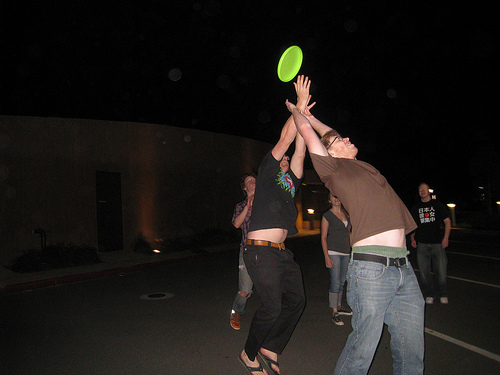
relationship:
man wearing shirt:
[288, 98, 425, 374] [310, 156, 416, 243]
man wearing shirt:
[244, 77, 316, 375] [245, 153, 301, 231]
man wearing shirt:
[416, 183, 452, 303] [416, 199, 451, 242]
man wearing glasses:
[288, 98, 425, 374] [326, 133, 342, 147]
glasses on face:
[326, 133, 342, 147] [327, 133, 359, 158]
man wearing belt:
[288, 98, 425, 374] [351, 252, 409, 265]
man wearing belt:
[244, 77, 316, 375] [245, 240, 290, 248]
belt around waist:
[351, 252, 409, 265] [350, 247, 413, 268]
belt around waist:
[245, 240, 290, 248] [243, 236, 292, 252]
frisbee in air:
[276, 44, 303, 81] [0, 1, 499, 230]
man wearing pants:
[244, 77, 316, 375] [243, 245, 306, 360]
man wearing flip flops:
[244, 77, 316, 375] [236, 351, 283, 374]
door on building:
[96, 168, 123, 255] [1, 118, 289, 248]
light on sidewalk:
[152, 250, 160, 255] [0, 252, 213, 282]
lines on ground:
[423, 246, 499, 362] [1, 232, 500, 374]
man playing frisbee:
[288, 98, 425, 374] [276, 44, 303, 81]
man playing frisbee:
[244, 77, 316, 375] [276, 44, 303, 81]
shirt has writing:
[416, 199, 451, 242] [417, 206, 435, 224]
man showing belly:
[288, 98, 425, 374] [354, 230, 408, 248]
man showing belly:
[244, 77, 316, 375] [248, 228, 285, 242]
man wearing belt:
[244, 77, 316, 375] [351, 252, 409, 265]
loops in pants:
[249, 239, 275, 247] [243, 245, 306, 360]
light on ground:
[152, 250, 160, 255] [1, 232, 500, 374]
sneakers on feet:
[424, 293, 447, 304] [425, 296, 446, 305]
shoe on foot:
[229, 312, 242, 328] [231, 312, 239, 330]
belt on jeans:
[351, 252, 409, 265] [334, 263, 424, 375]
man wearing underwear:
[288, 98, 425, 374] [353, 246, 407, 257]